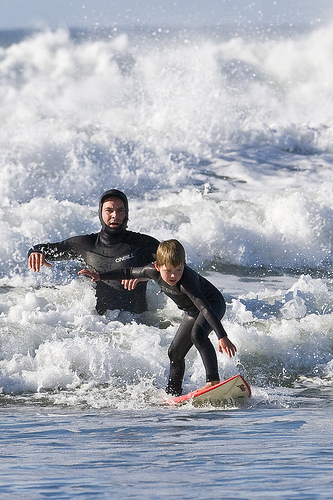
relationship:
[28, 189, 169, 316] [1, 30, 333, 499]
man in water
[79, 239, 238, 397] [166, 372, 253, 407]
boy on board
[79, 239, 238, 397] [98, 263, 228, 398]
boy wearing wetsuit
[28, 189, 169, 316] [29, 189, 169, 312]
man wearing wetsuit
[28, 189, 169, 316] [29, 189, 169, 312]
man in wetsuit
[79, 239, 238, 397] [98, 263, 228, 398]
boy in wetsuit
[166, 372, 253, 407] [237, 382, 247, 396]
board has logo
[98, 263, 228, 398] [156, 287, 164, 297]
wetsuit has zipper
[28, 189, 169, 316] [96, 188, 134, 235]
man has hood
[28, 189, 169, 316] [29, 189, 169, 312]
man has wetsuit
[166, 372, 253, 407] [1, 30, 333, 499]
board in water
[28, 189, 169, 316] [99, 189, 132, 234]
man has head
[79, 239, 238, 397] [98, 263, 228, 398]
boy has wetsuit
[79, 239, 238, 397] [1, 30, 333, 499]
boy in water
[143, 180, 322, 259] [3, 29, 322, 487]
waves crashing ocean